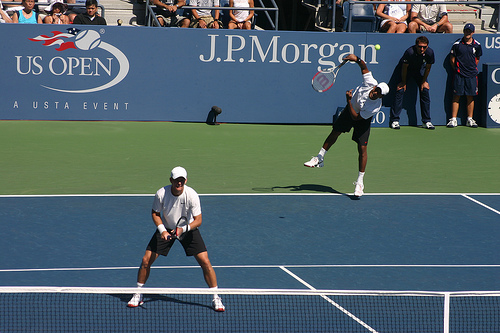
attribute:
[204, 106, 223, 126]
object — black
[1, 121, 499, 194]
asphalt — green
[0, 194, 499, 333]
court — blue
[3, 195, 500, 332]
asphalt — blue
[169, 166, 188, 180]
cap — white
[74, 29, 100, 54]
ball — white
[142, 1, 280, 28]
railing — blue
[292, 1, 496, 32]
railing — blue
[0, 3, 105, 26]
railing — blue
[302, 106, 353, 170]
leg — raised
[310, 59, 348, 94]
racket — white, black, red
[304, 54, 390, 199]
man — playing, jumping, participating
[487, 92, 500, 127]
clock — large, white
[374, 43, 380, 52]
ball — yellow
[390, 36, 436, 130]
man — standing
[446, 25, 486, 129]
man — standing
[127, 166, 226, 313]
man — playing, participating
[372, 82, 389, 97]
hat — white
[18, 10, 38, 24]
top — light, blue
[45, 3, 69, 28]
spectator — watching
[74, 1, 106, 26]
spectator — watching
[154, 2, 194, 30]
spectator — watching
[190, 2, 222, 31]
spectator — watching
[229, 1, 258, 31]
spectator — watching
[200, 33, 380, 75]
sign — displayed, white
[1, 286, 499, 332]
net — white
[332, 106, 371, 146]
shorts — black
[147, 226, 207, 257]
shorts — black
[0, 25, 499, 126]
wall — blue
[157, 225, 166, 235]
band — white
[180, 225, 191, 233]
band — white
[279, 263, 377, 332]
line — white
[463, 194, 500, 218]
line — white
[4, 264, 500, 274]
line — white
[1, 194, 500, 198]
line — white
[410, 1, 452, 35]
person — sitting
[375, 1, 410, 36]
person — sitting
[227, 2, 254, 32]
person — sitting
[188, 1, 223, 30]
person — sitting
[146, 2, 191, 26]
person — sitting